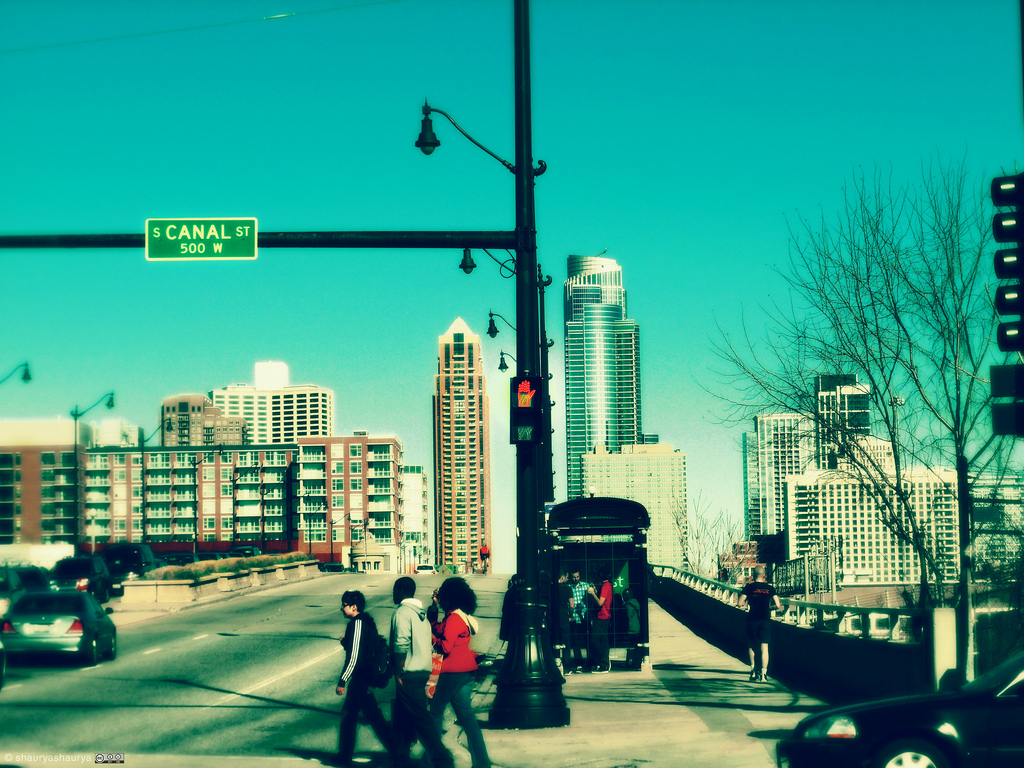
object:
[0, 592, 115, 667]
car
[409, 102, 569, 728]
street light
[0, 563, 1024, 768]
bridge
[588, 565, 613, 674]
man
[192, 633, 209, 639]
street marking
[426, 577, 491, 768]
people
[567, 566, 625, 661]
people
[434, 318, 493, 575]
building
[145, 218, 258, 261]
sign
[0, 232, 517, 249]
pole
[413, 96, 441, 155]
light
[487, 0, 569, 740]
pole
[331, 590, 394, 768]
woman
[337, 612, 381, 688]
black jacket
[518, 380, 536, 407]
red hand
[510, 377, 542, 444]
sign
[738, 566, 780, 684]
man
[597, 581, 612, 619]
red shirt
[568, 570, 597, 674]
person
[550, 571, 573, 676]
person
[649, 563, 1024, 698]
railing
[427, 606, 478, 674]
coat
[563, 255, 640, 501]
building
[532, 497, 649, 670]
shelter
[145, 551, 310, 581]
flowers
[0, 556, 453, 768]
roadside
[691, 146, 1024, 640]
bare tree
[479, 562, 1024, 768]
street corner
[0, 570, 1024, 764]
road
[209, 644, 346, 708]
lines